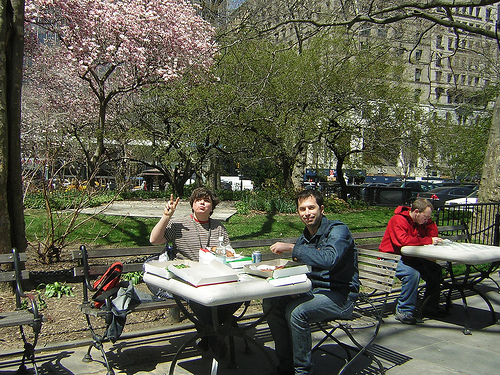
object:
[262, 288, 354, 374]
blue jeans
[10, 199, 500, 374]
ground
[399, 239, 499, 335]
table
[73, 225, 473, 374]
park bench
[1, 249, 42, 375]
park bench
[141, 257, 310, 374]
table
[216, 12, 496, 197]
building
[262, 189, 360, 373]
man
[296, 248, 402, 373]
chair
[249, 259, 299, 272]
food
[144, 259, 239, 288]
cardboard box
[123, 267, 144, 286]
green leaves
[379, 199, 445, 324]
man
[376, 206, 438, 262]
red sweater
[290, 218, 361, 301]
blue jacket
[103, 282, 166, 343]
jacket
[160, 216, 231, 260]
striped shirt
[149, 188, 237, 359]
boy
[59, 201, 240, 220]
slab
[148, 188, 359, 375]
two males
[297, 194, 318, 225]
face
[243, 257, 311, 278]
box